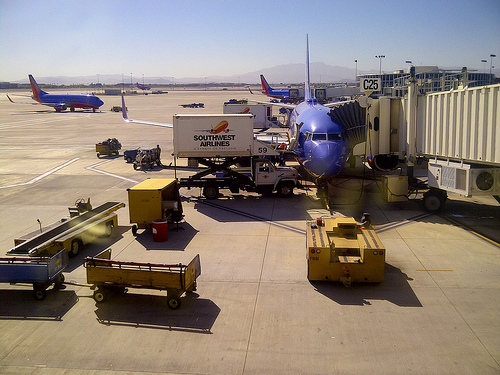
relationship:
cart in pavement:
[127, 172, 181, 227] [3, 86, 495, 374]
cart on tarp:
[126, 178, 186, 237] [0, 88, 497, 373]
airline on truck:
[184, 127, 244, 154] [170, 112, 283, 161]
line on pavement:
[24, 148, 59, 195] [0, 86, 500, 373]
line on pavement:
[81, 160, 130, 183] [0, 86, 500, 373]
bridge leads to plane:
[326, 65, 499, 216] [110, 17, 374, 195]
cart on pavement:
[0, 252, 71, 297] [3, 86, 495, 374]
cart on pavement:
[81, 248, 202, 310] [3, 86, 495, 374]